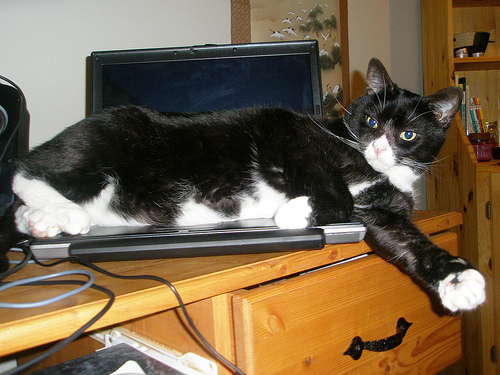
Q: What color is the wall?
A: White.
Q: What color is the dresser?
A: Brownish-tan.